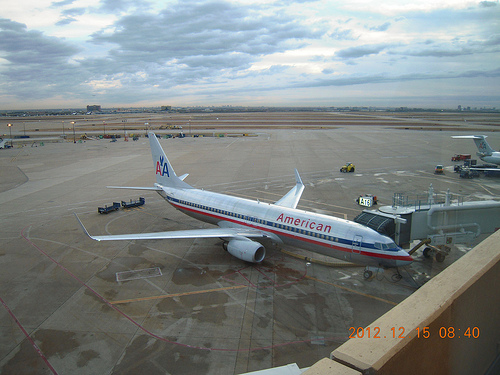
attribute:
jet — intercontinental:
[76, 125, 417, 274]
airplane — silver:
[58, 109, 420, 311]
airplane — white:
[77, 125, 424, 292]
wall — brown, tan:
[315, 221, 498, 366]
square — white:
[112, 264, 163, 284]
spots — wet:
[157, 287, 230, 326]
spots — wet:
[167, 264, 239, 283]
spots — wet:
[96, 253, 152, 284]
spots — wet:
[125, 243, 151, 258]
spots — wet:
[112, 330, 211, 373]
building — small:
[371, 177, 481, 250]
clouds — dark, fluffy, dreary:
[0, 1, 497, 108]